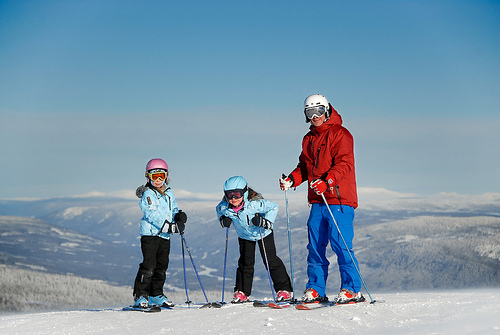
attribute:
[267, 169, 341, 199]
glove — white, red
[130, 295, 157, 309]
shoe — blue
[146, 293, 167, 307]
shoe — blue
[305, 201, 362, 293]
pants — blue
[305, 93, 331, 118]
helmet — white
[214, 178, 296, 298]
girl — leaning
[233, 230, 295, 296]
pants — black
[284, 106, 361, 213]
jacket — same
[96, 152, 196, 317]
girl — young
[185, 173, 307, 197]
helmet — blue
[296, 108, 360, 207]
coat — red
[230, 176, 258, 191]
helmet — blue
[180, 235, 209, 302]
poles — ski, blue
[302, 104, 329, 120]
goggles — black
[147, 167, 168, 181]
goggles — yellow, framed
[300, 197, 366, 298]
pants — blue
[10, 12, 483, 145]
sky — blue, clear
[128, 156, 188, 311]
girl — little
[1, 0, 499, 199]
sky — blue 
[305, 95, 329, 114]
helmet — white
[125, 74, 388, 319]
family — skiing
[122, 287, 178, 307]
boots — blue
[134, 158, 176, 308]
pants — black, snow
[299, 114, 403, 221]
jacket — red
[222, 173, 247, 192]
helmet — blue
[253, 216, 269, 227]
glove — black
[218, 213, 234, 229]
glove — black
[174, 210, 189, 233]
glove — black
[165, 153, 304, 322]
girl — bent forward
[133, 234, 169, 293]
pants — black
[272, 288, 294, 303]
boot — pink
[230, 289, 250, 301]
boot — pink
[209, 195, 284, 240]
jacket — girl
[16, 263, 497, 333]
mountain — snowy